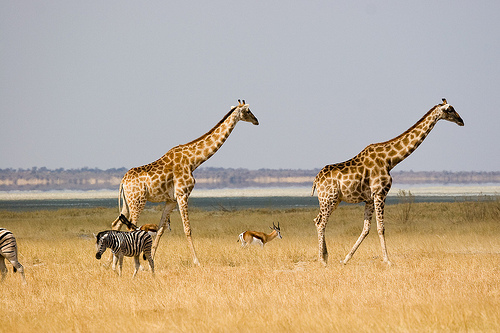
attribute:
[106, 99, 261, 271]
brown giraffe — tall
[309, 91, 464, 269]
giraffe — tall, brown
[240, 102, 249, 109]
ear — white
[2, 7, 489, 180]
sky — gray, smoggy